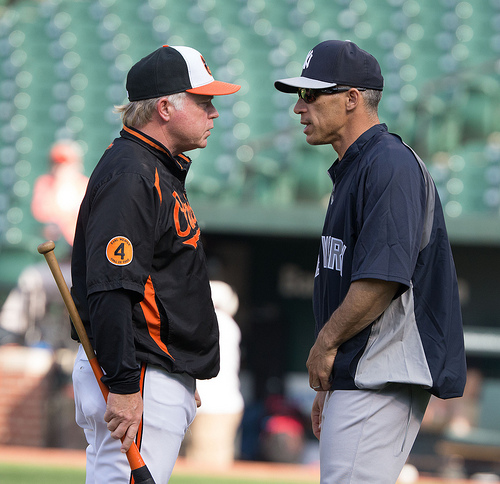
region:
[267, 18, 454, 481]
this is a man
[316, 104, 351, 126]
the man is light skinned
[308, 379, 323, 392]
this is a ring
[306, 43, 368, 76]
this is a cap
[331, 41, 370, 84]
the cap is black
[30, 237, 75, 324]
this is a bat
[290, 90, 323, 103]
this is a spectacle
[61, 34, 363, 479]
they are two men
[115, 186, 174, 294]
this is a jacket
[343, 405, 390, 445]
this is a trouser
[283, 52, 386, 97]
Person wearing baseball cap.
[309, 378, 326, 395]
Ring on man's finger.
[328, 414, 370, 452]
Man wearing gray pants.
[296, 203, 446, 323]
Man wearing gray and blue shirt.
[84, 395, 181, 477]
Man wearing white pants.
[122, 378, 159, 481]
Orange stripe down side of pants.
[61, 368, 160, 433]
Man holding baseball bat.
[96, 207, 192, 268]
Man wearing black and orange jacket.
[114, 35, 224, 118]
Person wearing baseball cap on head.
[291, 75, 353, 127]
Sunglasses on man's face.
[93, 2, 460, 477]
two men are talking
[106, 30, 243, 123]
the cap is maroon,white and blak in colour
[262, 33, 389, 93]
the cap is blac and white in colour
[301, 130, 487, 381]
the jacket is shortsleeved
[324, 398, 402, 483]
the pant is white in colour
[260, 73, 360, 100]
the man is wearing black gogles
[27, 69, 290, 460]
the man is holding a bat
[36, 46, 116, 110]
the seats are green in colour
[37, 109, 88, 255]
the person has a red shirt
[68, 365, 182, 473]
the pants are stripped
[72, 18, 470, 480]
the baseball coaches talk on the field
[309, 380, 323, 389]
the ring on the finger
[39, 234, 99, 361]
the wooden base of the bat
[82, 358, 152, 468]
the oragne handle of the bat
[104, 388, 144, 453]
the hand holding onto the bat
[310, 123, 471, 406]
the blue ajcket on the manager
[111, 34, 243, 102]
the white and black hat on the mans head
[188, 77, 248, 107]
the orange bill of the hat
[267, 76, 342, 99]
the white bill of the hat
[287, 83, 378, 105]
the sunglasses on the mans face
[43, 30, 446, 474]
two people that are facing each other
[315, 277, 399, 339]
the left arm of a person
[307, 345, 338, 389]
the left hand of a person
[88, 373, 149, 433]
the right hand of a person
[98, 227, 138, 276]
a number patch on a jacket sleeve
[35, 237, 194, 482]
a person holding a bat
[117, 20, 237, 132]
an orange, white and black baseball cap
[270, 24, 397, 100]
a black and white baseball cap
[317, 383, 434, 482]
a person wearing light grey pants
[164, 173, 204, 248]
a team name on the front of a jacket